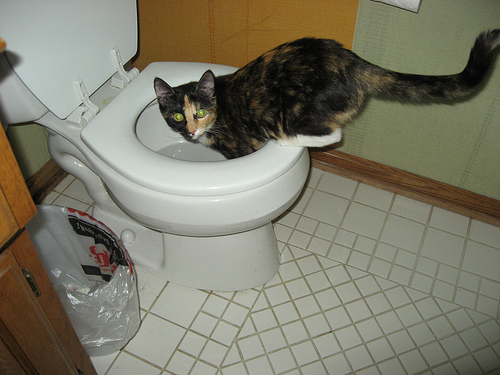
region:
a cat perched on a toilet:
[152, 26, 499, 157]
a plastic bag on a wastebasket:
[36, 204, 143, 356]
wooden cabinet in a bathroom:
[1, 128, 96, 374]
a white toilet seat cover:
[0, 0, 146, 115]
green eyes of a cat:
[174, 106, 206, 122]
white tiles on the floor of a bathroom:
[38, 166, 493, 371]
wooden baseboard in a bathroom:
[311, 143, 498, 231]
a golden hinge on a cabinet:
[24, 270, 41, 302]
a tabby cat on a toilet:
[151, 28, 497, 155]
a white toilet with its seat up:
[2, 2, 312, 296]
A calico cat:
[147, 24, 499, 165]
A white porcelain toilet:
[0, 1, 315, 298]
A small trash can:
[16, 201, 145, 363]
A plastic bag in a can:
[15, 196, 150, 361]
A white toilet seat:
[76, 54, 319, 203]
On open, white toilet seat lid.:
[2, 1, 139, 146]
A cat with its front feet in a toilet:
[149, 24, 499, 175]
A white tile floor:
[26, 166, 498, 372]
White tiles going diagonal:
[205, 240, 498, 374]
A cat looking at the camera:
[150, 27, 498, 162]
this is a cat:
[131, 30, 498, 128]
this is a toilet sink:
[98, 108, 162, 198]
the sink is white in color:
[201, 167, 263, 233]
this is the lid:
[36, 11, 105, 56]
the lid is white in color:
[45, 33, 107, 77]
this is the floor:
[290, 227, 402, 366]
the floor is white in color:
[331, 202, 391, 290]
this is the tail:
[386, 48, 485, 106]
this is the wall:
[158, 3, 242, 45]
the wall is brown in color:
[204, 6, 241, 23]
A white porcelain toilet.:
[5, 7, 295, 294]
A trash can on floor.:
[37, 199, 146, 349]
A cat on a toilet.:
[143, 36, 480, 146]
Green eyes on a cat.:
[165, 101, 207, 123]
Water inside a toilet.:
[159, 133, 232, 168]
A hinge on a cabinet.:
[18, 268, 46, 300]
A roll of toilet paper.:
[373, 1, 433, 15]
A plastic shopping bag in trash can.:
[45, 208, 134, 334]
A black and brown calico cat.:
[152, 55, 477, 152]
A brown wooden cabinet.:
[0, 136, 81, 373]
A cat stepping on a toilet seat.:
[154, 31, 497, 158]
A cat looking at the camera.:
[152, 26, 497, 158]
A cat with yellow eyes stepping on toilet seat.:
[151, 27, 496, 160]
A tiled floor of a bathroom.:
[49, 181, 490, 374]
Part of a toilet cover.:
[4, 3, 149, 120]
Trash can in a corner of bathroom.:
[36, 187, 140, 347]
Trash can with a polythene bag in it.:
[37, 202, 139, 351]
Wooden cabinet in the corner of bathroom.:
[0, 138, 88, 373]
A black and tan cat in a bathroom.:
[146, 25, 480, 162]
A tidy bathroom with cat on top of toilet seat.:
[0, 6, 492, 373]